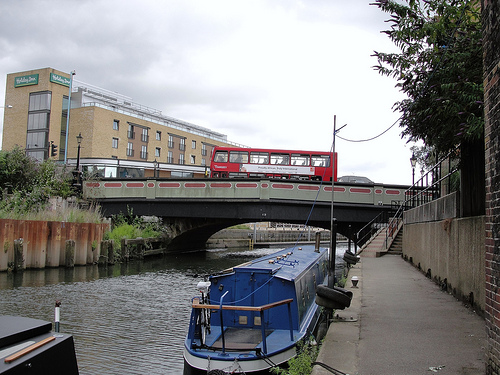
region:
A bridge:
[87, 152, 395, 239]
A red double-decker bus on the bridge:
[208, 138, 339, 188]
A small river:
[0, 230, 372, 372]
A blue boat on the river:
[173, 227, 348, 373]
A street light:
[56, 60, 88, 179]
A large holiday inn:
[12, 66, 252, 176]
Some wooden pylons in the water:
[7, 230, 142, 277]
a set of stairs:
[356, 204, 417, 255]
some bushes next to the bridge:
[1, 157, 88, 222]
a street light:
[399, 147, 435, 221]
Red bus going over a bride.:
[193, 137, 356, 190]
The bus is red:
[190, 135, 348, 185]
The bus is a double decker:
[193, 136, 342, 190]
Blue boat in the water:
[172, 230, 336, 372]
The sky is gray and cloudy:
[22, 0, 444, 188]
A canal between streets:
[6, 233, 382, 373]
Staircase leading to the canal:
[352, 201, 407, 270]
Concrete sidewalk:
[323, 228, 494, 368]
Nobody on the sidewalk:
[325, 219, 490, 369]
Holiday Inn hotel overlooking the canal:
[1, 60, 263, 197]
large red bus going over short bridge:
[198, 147, 355, 189]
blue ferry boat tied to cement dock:
[179, 240, 341, 372]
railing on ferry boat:
[183, 297, 296, 344]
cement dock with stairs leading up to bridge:
[341, 197, 471, 363]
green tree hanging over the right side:
[383, 0, 482, 185]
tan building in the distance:
[6, 58, 236, 160]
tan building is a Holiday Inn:
[6, 62, 82, 87]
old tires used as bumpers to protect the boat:
[313, 279, 363, 311]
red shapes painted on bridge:
[104, 179, 277, 203]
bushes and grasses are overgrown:
[86, 207, 169, 255]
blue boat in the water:
[173, 231, 338, 373]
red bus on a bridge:
[201, 144, 342, 182]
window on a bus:
[208, 146, 228, 166]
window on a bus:
[225, 148, 251, 165]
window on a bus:
[247, 148, 272, 167]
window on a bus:
[268, 149, 292, 169]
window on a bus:
[286, 149, 311, 169]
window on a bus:
[308, 150, 331, 170]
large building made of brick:
[2, 63, 276, 192]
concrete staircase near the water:
[351, 198, 413, 262]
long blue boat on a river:
[164, 223, 374, 371]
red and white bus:
[199, 123, 346, 196]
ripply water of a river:
[19, 249, 240, 366]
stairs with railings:
[353, 196, 410, 262]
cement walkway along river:
[342, 244, 465, 368]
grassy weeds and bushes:
[11, 167, 139, 245]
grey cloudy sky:
[45, 6, 356, 156]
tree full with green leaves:
[373, 6, 489, 187]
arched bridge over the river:
[143, 181, 384, 278]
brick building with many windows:
[16, 49, 234, 175]